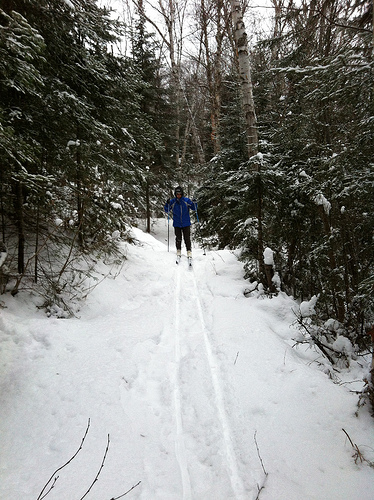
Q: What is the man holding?
A: Ski poles.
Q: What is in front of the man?
A: Ski tracks.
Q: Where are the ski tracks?
A: In the snow.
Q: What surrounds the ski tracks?
A: Trees.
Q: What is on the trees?
A: Snow.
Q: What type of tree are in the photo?
A: Pine.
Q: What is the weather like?
A: Snowy.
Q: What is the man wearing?
A: Blue and black ski outfit.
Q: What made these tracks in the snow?
A: A pair of skis.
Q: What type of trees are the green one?
A: Pine trees.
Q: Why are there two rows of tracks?
A: One row for each ski.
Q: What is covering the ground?
A: White snow.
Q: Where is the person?
A: A forest.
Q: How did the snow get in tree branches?
A: It stuck and froze there as it fell.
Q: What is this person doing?
A: Skiing in a forest.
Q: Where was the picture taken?
A: On a ski slope.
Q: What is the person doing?
A: Skiing.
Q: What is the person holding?
A: Poles.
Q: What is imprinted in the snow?
A: Tracks.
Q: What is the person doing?
A: Standing in snow.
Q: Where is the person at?
A: Woods.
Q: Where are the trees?
A: To the left and right.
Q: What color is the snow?
A: White.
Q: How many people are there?
A: One.